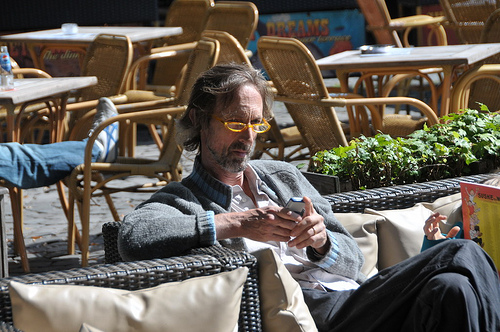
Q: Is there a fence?
A: No, there are no fences.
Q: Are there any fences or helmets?
A: No, there are no fences or helmets.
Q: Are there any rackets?
A: No, there are no rackets.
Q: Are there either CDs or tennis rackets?
A: No, there are no tennis rackets or cds.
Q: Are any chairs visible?
A: Yes, there is a chair.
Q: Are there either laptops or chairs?
A: Yes, there is a chair.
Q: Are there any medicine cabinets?
A: No, there are no medicine cabinets.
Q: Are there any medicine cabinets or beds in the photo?
A: No, there are no medicine cabinets or beds.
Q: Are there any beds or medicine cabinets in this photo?
A: No, there are no medicine cabinets or beds.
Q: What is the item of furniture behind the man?
A: The piece of furniture is a chair.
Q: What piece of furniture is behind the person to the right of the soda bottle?
A: The piece of furniture is a chair.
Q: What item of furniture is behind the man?
A: The piece of furniture is a chair.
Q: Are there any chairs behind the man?
A: Yes, there is a chair behind the man.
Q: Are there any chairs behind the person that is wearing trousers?
A: Yes, there is a chair behind the man.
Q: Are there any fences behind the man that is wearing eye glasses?
A: No, there is a chair behind the man.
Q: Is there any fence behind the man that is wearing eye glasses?
A: No, there is a chair behind the man.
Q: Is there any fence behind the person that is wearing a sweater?
A: No, there is a chair behind the man.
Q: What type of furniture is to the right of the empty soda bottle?
A: The piece of furniture is a chair.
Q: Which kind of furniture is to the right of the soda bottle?
A: The piece of furniture is a chair.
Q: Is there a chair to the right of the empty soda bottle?
A: Yes, there is a chair to the right of the soda bottle.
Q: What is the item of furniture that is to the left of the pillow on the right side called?
A: The piece of furniture is a chair.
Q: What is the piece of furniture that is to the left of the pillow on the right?
A: The piece of furniture is a chair.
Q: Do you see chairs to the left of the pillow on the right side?
A: Yes, there is a chair to the left of the pillow.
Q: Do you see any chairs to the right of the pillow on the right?
A: No, the chair is to the left of the pillow.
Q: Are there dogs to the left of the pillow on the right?
A: No, there is a chair to the left of the pillow.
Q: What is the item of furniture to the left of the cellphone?
A: The piece of furniture is a chair.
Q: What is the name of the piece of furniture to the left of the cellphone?
A: The piece of furniture is a chair.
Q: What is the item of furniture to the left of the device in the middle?
A: The piece of furniture is a chair.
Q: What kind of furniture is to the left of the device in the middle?
A: The piece of furniture is a chair.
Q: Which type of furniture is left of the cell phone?
A: The piece of furniture is a chair.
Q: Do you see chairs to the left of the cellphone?
A: Yes, there is a chair to the left of the cellphone.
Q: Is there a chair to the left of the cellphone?
A: Yes, there is a chair to the left of the cellphone.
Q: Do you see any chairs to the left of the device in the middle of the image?
A: Yes, there is a chair to the left of the cellphone.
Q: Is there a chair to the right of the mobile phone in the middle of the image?
A: No, the chair is to the left of the mobile phone.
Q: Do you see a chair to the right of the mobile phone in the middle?
A: No, the chair is to the left of the mobile phone.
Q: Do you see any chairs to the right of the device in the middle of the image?
A: No, the chair is to the left of the mobile phone.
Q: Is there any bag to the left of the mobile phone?
A: No, there is a chair to the left of the mobile phone.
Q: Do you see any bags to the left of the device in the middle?
A: No, there is a chair to the left of the mobile phone.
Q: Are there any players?
A: No, there are no players.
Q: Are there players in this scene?
A: No, there are no players.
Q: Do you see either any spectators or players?
A: No, there are no players or spectators.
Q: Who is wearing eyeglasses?
A: The man is wearing eyeglasses.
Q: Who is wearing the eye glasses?
A: The man is wearing eyeglasses.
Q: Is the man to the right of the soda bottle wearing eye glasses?
A: Yes, the man is wearing eye glasses.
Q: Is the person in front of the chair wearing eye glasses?
A: Yes, the man is wearing eye glasses.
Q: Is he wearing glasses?
A: No, the man is wearing eye glasses.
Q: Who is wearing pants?
A: The man is wearing pants.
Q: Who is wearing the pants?
A: The man is wearing pants.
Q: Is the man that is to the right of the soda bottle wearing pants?
A: Yes, the man is wearing pants.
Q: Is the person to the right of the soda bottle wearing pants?
A: Yes, the man is wearing pants.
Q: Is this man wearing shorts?
A: No, the man is wearing pants.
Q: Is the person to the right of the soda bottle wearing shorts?
A: No, the man is wearing pants.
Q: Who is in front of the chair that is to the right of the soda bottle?
A: The man is in front of the chair.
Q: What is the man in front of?
A: The man is in front of the chair.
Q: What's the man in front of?
A: The man is in front of the chair.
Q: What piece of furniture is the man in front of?
A: The man is in front of the chair.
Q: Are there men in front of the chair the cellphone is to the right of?
A: Yes, there is a man in front of the chair.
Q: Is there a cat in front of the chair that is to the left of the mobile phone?
A: No, there is a man in front of the chair.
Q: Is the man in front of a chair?
A: Yes, the man is in front of a chair.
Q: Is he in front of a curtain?
A: No, the man is in front of a chair.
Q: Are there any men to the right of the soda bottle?
A: Yes, there is a man to the right of the soda bottle.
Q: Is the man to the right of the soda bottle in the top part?
A: Yes, the man is to the right of the soda bottle.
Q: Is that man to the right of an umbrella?
A: No, the man is to the right of the soda bottle.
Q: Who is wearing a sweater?
A: The man is wearing a sweater.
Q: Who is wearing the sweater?
A: The man is wearing a sweater.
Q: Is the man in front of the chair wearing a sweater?
A: Yes, the man is wearing a sweater.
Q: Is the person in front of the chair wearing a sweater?
A: Yes, the man is wearing a sweater.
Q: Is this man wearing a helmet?
A: No, the man is wearing a sweater.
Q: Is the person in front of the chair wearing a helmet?
A: No, the man is wearing a sweater.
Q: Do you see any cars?
A: No, there are no cars.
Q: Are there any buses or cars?
A: No, there are no cars or buses.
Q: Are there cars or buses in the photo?
A: No, there are no cars or buses.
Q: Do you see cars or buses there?
A: No, there are no cars or buses.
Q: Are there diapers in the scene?
A: No, there are no diapers.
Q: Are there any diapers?
A: No, there are no diapers.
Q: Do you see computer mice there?
A: No, there are no computer mice.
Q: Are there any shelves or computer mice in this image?
A: No, there are no computer mice or shelves.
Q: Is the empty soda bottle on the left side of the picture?
A: Yes, the soda bottle is on the left of the image.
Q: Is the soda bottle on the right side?
A: No, the soda bottle is on the left of the image.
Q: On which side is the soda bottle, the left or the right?
A: The soda bottle is on the left of the image.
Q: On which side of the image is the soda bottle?
A: The soda bottle is on the left of the image.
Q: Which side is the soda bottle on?
A: The soda bottle is on the left of the image.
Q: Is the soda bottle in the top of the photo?
A: Yes, the soda bottle is in the top of the image.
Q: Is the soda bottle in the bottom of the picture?
A: No, the soda bottle is in the top of the image.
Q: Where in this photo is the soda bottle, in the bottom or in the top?
A: The soda bottle is in the top of the image.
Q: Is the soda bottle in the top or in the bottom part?
A: The soda bottle is in the top of the image.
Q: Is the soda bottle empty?
A: Yes, the soda bottle is empty.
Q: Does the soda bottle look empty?
A: Yes, the soda bottle is empty.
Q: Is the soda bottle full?
A: No, the soda bottle is empty.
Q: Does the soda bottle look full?
A: No, the soda bottle is empty.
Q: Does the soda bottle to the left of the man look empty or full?
A: The soda bottle is empty.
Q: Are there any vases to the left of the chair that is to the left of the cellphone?
A: No, there is a soda bottle to the left of the chair.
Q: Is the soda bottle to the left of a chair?
A: Yes, the soda bottle is to the left of a chair.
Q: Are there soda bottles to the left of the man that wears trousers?
A: Yes, there is a soda bottle to the left of the man.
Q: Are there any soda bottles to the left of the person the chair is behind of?
A: Yes, there is a soda bottle to the left of the man.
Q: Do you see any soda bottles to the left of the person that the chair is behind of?
A: Yes, there is a soda bottle to the left of the man.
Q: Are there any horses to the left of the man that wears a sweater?
A: No, there is a soda bottle to the left of the man.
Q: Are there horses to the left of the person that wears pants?
A: No, there is a soda bottle to the left of the man.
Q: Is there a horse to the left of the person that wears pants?
A: No, there is a soda bottle to the left of the man.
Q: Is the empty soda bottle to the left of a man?
A: Yes, the soda bottle is to the left of a man.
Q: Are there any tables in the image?
A: Yes, there is a table.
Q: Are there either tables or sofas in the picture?
A: Yes, there is a table.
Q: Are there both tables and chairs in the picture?
A: Yes, there are both a table and a chair.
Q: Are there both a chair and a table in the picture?
A: Yes, there are both a table and a chair.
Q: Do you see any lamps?
A: No, there are no lamps.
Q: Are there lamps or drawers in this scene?
A: No, there are no lamps or drawers.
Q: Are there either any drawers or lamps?
A: No, there are no lamps or drawers.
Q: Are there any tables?
A: Yes, there is a table.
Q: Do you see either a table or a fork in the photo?
A: Yes, there is a table.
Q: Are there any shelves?
A: No, there are no shelves.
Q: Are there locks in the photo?
A: No, there are no locks.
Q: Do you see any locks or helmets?
A: No, there are no locks or helmets.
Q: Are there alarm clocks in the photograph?
A: No, there are no alarm clocks.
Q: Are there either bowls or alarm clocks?
A: No, there are no alarm clocks or bowls.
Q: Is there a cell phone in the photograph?
A: Yes, there is a cell phone.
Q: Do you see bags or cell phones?
A: Yes, there is a cell phone.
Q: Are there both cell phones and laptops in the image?
A: No, there is a cell phone but no laptops.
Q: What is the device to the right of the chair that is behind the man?
A: The device is a cell phone.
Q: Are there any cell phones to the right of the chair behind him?
A: Yes, there is a cell phone to the right of the chair.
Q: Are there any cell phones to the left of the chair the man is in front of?
A: No, the cell phone is to the right of the chair.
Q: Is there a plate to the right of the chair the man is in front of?
A: No, there is a cell phone to the right of the chair.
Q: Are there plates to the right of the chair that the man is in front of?
A: No, there is a cell phone to the right of the chair.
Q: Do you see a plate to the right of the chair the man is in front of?
A: No, there is a cell phone to the right of the chair.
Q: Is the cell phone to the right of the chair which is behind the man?
A: Yes, the cell phone is to the right of the chair.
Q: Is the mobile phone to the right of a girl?
A: No, the mobile phone is to the right of the chair.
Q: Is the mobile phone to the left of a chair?
A: No, the mobile phone is to the right of a chair.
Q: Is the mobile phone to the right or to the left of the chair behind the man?
A: The mobile phone is to the right of the chair.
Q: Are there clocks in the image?
A: No, there are no clocks.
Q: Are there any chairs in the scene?
A: Yes, there is a chair.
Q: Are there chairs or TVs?
A: Yes, there is a chair.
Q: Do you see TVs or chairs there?
A: Yes, there is a chair.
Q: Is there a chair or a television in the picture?
A: Yes, there is a chair.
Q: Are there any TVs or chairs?
A: Yes, there is a chair.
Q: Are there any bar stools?
A: No, there are no bar stools.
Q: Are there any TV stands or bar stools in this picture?
A: No, there are no bar stools or TV stands.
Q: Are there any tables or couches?
A: Yes, there is a table.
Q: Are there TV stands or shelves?
A: No, there are no shelves or TV stands.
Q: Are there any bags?
A: No, there are no bags.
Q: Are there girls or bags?
A: No, there are no bags or girls.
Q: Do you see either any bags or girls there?
A: No, there are no bags or girls.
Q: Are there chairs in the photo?
A: Yes, there is a chair.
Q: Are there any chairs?
A: Yes, there is a chair.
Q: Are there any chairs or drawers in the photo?
A: Yes, there is a chair.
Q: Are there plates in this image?
A: No, there are no plates.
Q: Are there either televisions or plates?
A: No, there are no plates or televisions.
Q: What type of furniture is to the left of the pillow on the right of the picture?
A: The piece of furniture is a chair.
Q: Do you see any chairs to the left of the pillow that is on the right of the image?
A: Yes, there is a chair to the left of the pillow.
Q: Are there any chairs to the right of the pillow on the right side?
A: No, the chair is to the left of the pillow.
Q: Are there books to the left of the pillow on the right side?
A: No, there is a chair to the left of the pillow.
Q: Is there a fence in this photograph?
A: No, there are no fences.